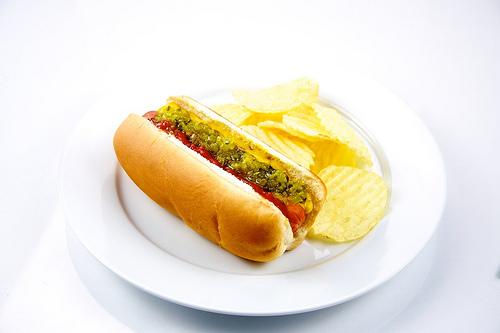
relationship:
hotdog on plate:
[112, 95, 327, 264] [64, 81, 449, 323]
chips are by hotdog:
[215, 77, 390, 243] [112, 95, 327, 264]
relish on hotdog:
[163, 106, 316, 208] [112, 95, 327, 264]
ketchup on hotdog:
[153, 119, 290, 218] [112, 95, 327, 264]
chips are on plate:
[215, 77, 390, 243] [64, 81, 449, 323]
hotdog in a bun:
[112, 95, 327, 264] [121, 114, 287, 267]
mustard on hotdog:
[200, 117, 231, 136] [112, 95, 327, 264]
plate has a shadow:
[64, 81, 449, 323] [55, 223, 467, 332]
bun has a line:
[121, 114, 287, 267] [209, 210, 225, 245]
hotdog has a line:
[112, 95, 327, 264] [294, 212, 302, 223]